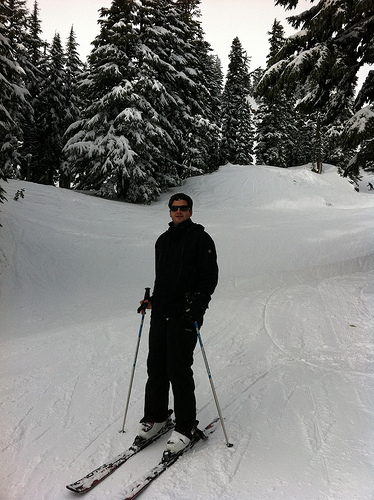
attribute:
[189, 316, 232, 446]
ski pole — white, blue, silver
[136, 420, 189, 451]
boots — white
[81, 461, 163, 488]
skis — black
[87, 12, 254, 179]
trees — tall, green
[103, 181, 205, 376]
man — skiing, standing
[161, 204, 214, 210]
sunglasses — black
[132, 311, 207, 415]
pants — black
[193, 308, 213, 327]
glove — black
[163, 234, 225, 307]
coat — black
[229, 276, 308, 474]
slope — snowy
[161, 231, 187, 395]
snow gear — black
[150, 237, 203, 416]
clothing — black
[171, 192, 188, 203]
hair — black, short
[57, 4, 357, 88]
sky — grey